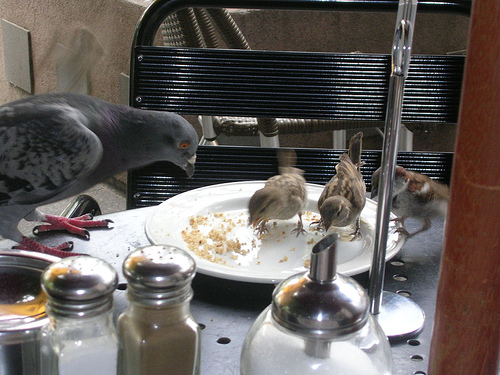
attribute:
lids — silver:
[36, 239, 196, 316]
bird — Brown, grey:
[0, 92, 197, 260]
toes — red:
[12, 203, 152, 274]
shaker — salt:
[35, 252, 118, 373]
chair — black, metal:
[132, 10, 481, 249]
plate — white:
[125, 195, 210, 247]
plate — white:
[142, 173, 414, 295]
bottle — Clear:
[36, 255, 121, 374]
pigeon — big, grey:
[2, 90, 199, 259]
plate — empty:
[144, 173, 402, 281]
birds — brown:
[238, 144, 481, 253]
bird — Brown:
[259, 174, 325, 238]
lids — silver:
[38, 249, 197, 311]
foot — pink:
[41, 203, 103, 246]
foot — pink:
[8, 232, 86, 274]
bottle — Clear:
[237, 225, 394, 374]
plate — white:
[155, 183, 394, 287]